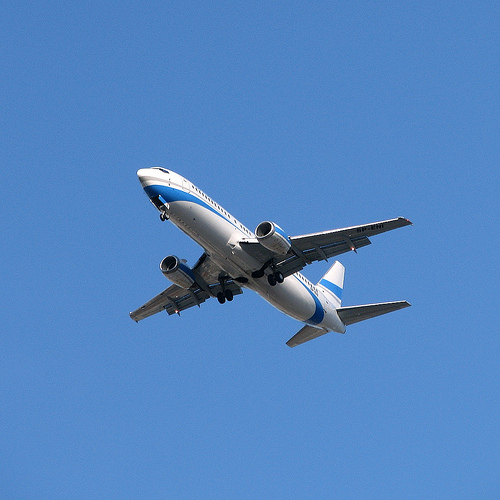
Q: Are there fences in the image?
A: No, there are no fences.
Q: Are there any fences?
A: No, there are no fences.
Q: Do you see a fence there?
A: No, there are no fences.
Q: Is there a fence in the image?
A: No, there are no fences.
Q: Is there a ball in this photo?
A: No, there are no balls.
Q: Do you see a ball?
A: No, there are no balls.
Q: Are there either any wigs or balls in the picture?
A: No, there are no balls or wigs.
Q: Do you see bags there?
A: No, there are no bags.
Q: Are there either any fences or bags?
A: No, there are no bags or fences.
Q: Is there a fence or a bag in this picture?
A: No, there are no bags or fences.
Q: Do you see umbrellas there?
A: No, there are no umbrellas.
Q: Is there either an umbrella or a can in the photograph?
A: No, there are no umbrellas or cans.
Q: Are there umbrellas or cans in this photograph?
A: No, there are no umbrellas or cans.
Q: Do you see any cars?
A: No, there are no cars.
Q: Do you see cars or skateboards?
A: No, there are no cars or skateboards.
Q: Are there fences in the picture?
A: No, there are no fences.